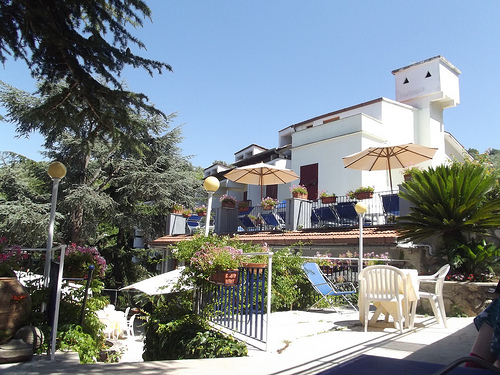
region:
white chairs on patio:
[331, 254, 463, 352]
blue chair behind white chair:
[272, 236, 344, 325]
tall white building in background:
[190, 56, 482, 173]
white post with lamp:
[26, 157, 83, 339]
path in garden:
[117, 281, 153, 371]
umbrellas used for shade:
[232, 144, 438, 190]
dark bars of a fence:
[188, 254, 292, 345]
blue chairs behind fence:
[289, 186, 406, 226]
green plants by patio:
[186, 174, 298, 281]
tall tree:
[44, 124, 189, 279]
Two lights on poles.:
[25, 150, 247, 210]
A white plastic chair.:
[330, 250, 425, 345]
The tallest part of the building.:
[375, 45, 470, 110]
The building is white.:
[190, 26, 480, 201]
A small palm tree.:
[395, 158, 496, 279]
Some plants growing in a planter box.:
[176, 236, 242, 286]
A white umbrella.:
[336, 127, 436, 224]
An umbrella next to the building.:
[211, 143, 316, 224]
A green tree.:
[0, 0, 185, 138]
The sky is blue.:
[204, 13, 369, 75]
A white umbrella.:
[332, 127, 438, 172]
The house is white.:
[248, 45, 483, 161]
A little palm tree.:
[393, 152, 498, 262]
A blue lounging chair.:
[292, 255, 357, 316]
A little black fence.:
[190, 260, 280, 345]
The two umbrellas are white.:
[211, 135, 442, 181]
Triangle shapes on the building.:
[400, 62, 436, 88]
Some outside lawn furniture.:
[295, 252, 466, 332]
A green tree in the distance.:
[15, 73, 181, 155]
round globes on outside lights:
[25, 151, 84, 373]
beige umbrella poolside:
[225, 156, 304, 236]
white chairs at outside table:
[347, 241, 474, 356]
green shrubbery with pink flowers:
[59, 229, 111, 295]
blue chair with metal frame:
[305, 255, 373, 351]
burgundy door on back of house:
[296, 153, 326, 215]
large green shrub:
[396, 154, 498, 302]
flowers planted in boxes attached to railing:
[309, 185, 390, 219]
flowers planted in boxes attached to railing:
[190, 235, 285, 321]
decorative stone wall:
[425, 266, 496, 329]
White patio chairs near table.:
[368, 262, 499, 314]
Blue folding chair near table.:
[312, 254, 377, 341]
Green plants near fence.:
[163, 300, 245, 372]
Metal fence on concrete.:
[205, 223, 282, 283]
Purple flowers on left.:
[35, 243, 142, 279]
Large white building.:
[274, 132, 448, 246]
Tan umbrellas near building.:
[213, 156, 498, 193]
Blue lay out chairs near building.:
[230, 201, 392, 232]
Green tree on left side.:
[51, 130, 150, 239]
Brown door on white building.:
[286, 157, 341, 208]